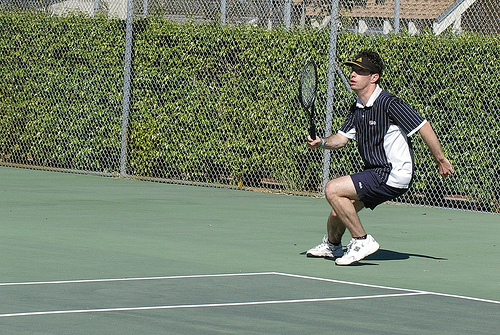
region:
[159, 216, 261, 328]
A white line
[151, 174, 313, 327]
A white line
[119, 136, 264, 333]
A white line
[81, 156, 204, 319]
A white line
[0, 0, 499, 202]
a chain link fence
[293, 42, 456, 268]
a male tennis player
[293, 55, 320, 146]
a black tennis racket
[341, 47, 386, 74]
a black tennis hat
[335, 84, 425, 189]
a black and white shirt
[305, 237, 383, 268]
a pair of white tennis shoes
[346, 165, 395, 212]
a pair of men's dark shorts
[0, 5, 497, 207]
a long green hedge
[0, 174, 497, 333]
a green tennis court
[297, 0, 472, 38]
a brown roof with white beams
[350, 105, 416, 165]
man wearing black and white shirt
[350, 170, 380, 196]
man wearing black shorts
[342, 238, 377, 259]
man wearing white shoe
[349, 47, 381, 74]
man wearing black and gold visor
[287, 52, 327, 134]
man holding black tennis racquet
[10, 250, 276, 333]
green and white tennis court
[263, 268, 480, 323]
green and white tennis court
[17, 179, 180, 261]
green tennis court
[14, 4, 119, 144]
green bushes behind metal fence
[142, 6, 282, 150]
green bushes behind metal fence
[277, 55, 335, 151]
a black tennis racket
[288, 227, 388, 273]
white tennis shoes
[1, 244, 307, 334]
white lines on the tennis court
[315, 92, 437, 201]
black and white striped shirt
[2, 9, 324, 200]
green bushes outside the fence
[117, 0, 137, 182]
silver pole holding the chain links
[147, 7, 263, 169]
chain link fence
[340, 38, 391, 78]
tennis player's visor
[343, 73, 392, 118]
white collar of a polo shirt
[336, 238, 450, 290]
shadow of the tennis player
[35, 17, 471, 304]
man in action playing tennis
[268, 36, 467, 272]
he is getting ready to return a serve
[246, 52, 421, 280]
he is poised and ready to play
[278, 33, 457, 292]
the man is wearing black and white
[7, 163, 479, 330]
the tennis court is green and grey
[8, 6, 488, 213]
a fence behind the player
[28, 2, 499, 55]
houses behind the fence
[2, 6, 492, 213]
bushes block the view of the neighborhood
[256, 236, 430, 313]
white tennis shoes on his feet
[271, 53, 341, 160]
a black raquet in his hand